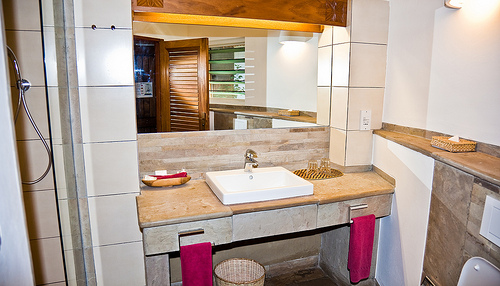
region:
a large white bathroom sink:
[202, 163, 316, 203]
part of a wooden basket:
[209, 257, 271, 284]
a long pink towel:
[347, 215, 376, 283]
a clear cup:
[317, 155, 334, 173]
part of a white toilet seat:
[455, 257, 498, 284]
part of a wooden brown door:
[162, 36, 209, 130]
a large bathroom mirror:
[132, 19, 334, 135]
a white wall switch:
[357, 106, 372, 132]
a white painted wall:
[442, 13, 498, 124]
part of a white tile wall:
[75, 26, 133, 87]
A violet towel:
[179, 242, 215, 284]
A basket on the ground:
[212, 257, 267, 284]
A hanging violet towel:
[348, 213, 374, 281]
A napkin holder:
[427, 134, 476, 152]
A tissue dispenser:
[431, 133, 474, 153]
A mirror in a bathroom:
[131, 16, 323, 133]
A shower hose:
[5, 45, 51, 187]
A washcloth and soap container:
[141, 166, 189, 187]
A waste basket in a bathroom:
[213, 257, 265, 284]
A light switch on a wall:
[359, 107, 372, 131]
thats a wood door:
[155, 37, 210, 133]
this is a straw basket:
[212, 253, 267, 285]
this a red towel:
[347, 212, 378, 284]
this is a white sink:
[202, 148, 317, 208]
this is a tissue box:
[429, 133, 479, 155]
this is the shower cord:
[0, 41, 51, 188]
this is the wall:
[325, 0, 392, 177]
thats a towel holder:
[175, 226, 210, 246]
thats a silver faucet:
[243, 147, 263, 167]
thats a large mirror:
[138, 20, 334, 132]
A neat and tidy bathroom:
[1, 1, 498, 282]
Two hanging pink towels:
[179, 210, 378, 283]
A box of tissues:
[425, 128, 481, 157]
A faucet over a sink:
[201, 147, 316, 207]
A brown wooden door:
[152, 34, 214, 134]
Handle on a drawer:
[344, 198, 373, 215]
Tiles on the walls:
[1, 0, 390, 283]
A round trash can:
[213, 254, 269, 282]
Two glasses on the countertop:
[301, 153, 341, 179]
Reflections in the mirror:
[131, 11, 335, 132]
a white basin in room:
[162, 155, 300, 210]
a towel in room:
[343, 213, 390, 282]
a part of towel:
[178, 227, 212, 264]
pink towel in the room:
[342, 218, 384, 281]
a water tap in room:
[231, 143, 281, 195]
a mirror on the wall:
[161, 13, 328, 111]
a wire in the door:
[19, 118, 74, 192]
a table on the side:
[388, 107, 497, 165]